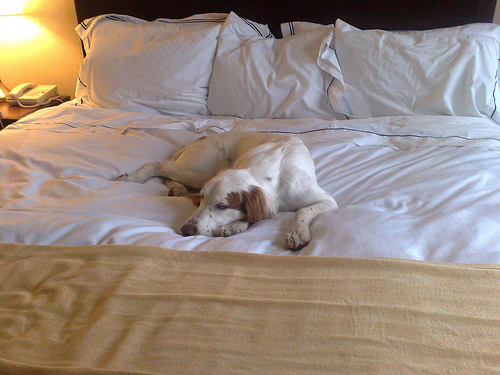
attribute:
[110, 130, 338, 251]
dog — sleeping, white, brown, laying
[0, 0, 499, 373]
bed — large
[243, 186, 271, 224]
ear — brown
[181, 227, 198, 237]
nose — black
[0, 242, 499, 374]
blanket — brown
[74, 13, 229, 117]
pillow — white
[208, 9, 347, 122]
pillow — white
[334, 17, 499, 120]
pillow — white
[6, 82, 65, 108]
phone — white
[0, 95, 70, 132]
nightstand — wooden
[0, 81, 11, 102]
lamp — on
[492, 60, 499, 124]
stripe — blue